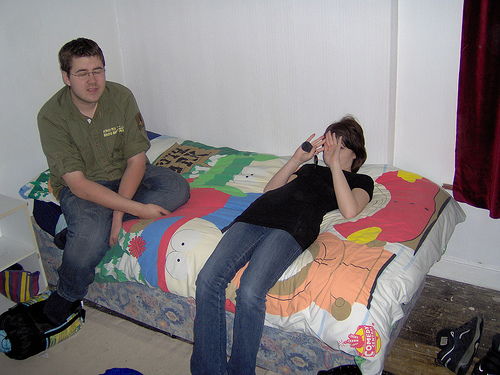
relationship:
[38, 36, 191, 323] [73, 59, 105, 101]
man has face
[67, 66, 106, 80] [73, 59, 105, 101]
glasses on front of face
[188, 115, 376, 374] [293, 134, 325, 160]
woman has hand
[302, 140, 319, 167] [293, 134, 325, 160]
sunglasses held in hand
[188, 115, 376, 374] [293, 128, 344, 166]
woman has hands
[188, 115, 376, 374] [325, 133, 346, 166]
woman has face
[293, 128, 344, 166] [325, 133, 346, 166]
hands over face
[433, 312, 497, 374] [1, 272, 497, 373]
shoes on top of floor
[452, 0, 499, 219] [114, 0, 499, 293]
curtain hanging on wall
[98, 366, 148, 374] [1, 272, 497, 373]
shirt on top of floor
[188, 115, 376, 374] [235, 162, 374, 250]
woman wearing shirt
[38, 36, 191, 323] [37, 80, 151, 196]
man wearing shirt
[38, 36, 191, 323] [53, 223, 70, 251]
man wearing sock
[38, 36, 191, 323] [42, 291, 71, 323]
man wearing sock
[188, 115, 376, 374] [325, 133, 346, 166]
woman hiding face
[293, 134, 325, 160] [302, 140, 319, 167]
hand holding sunglasses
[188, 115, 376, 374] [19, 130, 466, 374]
woman on top of bed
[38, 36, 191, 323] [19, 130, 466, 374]
man on top of bed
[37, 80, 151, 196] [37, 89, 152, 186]
shirt has sleeves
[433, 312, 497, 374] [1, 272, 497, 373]
shoes sitting on floor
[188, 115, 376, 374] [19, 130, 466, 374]
woman laying across bed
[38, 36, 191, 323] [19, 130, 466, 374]
man sitting on bed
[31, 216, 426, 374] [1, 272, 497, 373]
box spring on top of floor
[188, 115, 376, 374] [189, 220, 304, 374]
woman wearing jeans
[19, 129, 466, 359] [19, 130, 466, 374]
comforter on top of bed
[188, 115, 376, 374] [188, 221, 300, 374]
woman has legs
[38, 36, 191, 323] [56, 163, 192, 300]
man has legs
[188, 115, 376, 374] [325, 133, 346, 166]
woman covering face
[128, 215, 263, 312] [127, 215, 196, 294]
cartoon character wearing hat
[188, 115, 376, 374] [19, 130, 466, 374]
woman laying on bed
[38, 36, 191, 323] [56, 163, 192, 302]
man wearing jeans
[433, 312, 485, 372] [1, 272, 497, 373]
shoes on top of floor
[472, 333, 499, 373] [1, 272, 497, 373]
shoe on top of floor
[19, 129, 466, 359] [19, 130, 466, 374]
comforter o top of bed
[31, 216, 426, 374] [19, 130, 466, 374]
box spring udereath bed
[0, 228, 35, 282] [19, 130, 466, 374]
shelf ext to bed